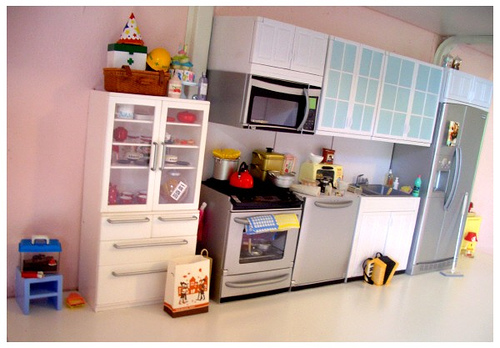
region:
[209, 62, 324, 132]
Microwave under the cabinet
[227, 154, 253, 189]
red tea kettle on the stove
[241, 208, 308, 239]
towel on a stove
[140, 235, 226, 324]
bag in front of a cabinet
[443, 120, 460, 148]
Picture on a refrigerator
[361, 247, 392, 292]
case on the floor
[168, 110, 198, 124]
red bowl in the cabinet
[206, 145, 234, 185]
pot on the stove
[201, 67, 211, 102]
bottle on the cabinet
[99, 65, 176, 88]
basket on top of the cabinet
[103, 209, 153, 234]
Silver handle on drawer.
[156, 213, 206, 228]
Silver handle on drawer.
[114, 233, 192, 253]
Silver handle on drawer.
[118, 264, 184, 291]
Silver handle on drawer.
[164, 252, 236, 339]
Bag sitting on floor.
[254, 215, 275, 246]
Blue and white towel on oven.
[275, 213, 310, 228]
Yellow towel on oven.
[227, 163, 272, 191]
Red tea kettle on top of stove.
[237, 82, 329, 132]
Black and silver built in microwave.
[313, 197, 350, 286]
Silver dishwasher in room.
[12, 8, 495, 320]
So colorful, this kitchen may be a dollhouse.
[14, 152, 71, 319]
A pink wall with a blue stool.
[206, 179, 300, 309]
A stove with 2 towels hanging from the door.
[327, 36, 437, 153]
White and pale mint colored cabinets.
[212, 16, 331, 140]
A microwave beneath a cabinet.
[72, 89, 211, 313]
This cabinet has clear doors on the upper section.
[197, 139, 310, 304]
Pots rest upon the stove.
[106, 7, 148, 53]
Red, white, blue and yellow adorn a party hat.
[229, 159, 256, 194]
A red teapot with a black handle.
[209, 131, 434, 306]
A kitchen area lacking counter space.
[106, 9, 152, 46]
birthday party hat with stars and dots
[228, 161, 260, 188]
red whistle tea pot on stove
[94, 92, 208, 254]
white cabinet filled with dishes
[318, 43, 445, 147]
cabinets have blue squares inset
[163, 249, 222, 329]
shopping bag sitting on floor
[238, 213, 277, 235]
blue and white towel resting on oven handle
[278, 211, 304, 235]
yellow and white towel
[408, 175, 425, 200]
blue bottle sitting on the edge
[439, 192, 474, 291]
mop is propped up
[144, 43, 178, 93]
yellow hard hat placed in basket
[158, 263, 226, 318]
A shopping bag on the flower.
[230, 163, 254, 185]
A red teapot on the stove.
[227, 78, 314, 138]
A microwave above the stove.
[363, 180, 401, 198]
A silver sink in the kitchen.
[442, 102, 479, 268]
A refrigerator in the kitchen.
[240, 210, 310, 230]
Towel over the oven door.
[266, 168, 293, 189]
A pot on the stove burner.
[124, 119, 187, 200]
Dishes in the cabinet.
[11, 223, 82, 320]
A toy next to the cabinet.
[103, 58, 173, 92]
A basket on top of the cabinet.